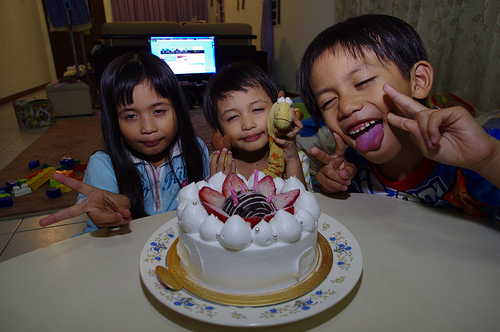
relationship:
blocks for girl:
[0, 154, 84, 211] [39, 52, 211, 230]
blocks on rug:
[9, 156, 88, 238] [17, 160, 100, 228]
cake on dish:
[159, 170, 313, 264] [135, 213, 365, 329]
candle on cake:
[214, 182, 245, 207] [159, 170, 313, 264]